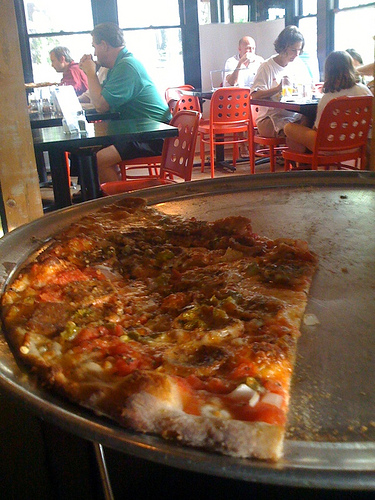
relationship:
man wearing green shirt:
[76, 22, 176, 191] [98, 46, 174, 134]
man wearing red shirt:
[48, 47, 91, 97] [60, 60, 88, 96]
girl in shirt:
[260, 20, 330, 115] [258, 55, 337, 103]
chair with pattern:
[97, 108, 205, 198] [170, 120, 195, 169]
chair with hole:
[97, 108, 205, 198] [175, 121, 183, 131]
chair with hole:
[97, 108, 205, 198] [171, 136, 178, 144]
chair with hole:
[97, 108, 205, 198] [181, 138, 185, 147]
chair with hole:
[97, 108, 205, 198] [185, 139, 189, 146]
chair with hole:
[97, 108, 205, 198] [178, 153, 184, 164]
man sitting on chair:
[76, 22, 176, 191] [119, 93, 202, 179]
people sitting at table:
[248, 19, 370, 170] [239, 76, 354, 163]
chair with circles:
[208, 88, 246, 135] [212, 93, 252, 120]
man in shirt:
[76, 22, 176, 191] [93, 55, 156, 115]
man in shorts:
[76, 22, 176, 191] [111, 138, 159, 153]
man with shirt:
[48, 47, 90, 103] [62, 64, 89, 91]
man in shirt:
[76, 22, 176, 191] [221, 56, 268, 94]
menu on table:
[46, 84, 91, 135] [23, 76, 213, 187]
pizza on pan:
[1, 195, 321, 462] [1, 168, 373, 489]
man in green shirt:
[76, 22, 176, 191] [94, 49, 173, 119]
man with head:
[216, 29, 267, 97] [233, 32, 258, 65]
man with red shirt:
[48, 47, 90, 103] [60, 65, 90, 88]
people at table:
[248, 24, 373, 170] [231, 75, 364, 118]